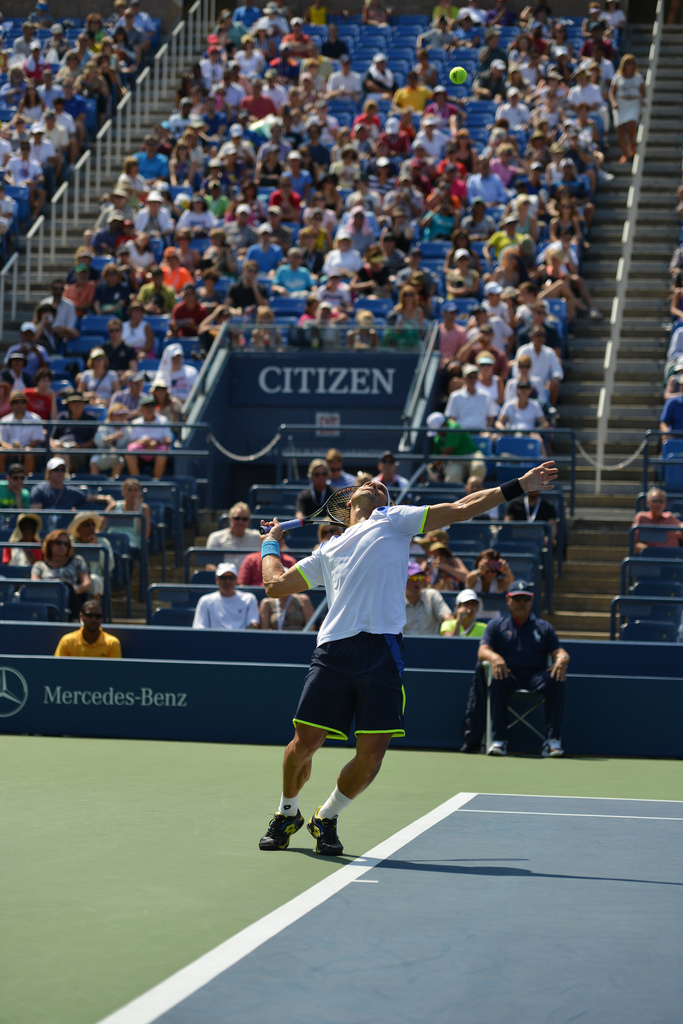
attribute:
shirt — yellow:
[36, 584, 112, 654]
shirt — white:
[173, 539, 274, 636]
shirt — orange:
[138, 238, 194, 312]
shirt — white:
[71, 521, 147, 573]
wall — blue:
[36, 654, 209, 735]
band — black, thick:
[473, 469, 541, 513]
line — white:
[126, 787, 660, 1013]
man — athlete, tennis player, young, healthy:
[327, 465, 461, 613]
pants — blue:
[288, 631, 444, 794]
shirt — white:
[255, 469, 508, 691]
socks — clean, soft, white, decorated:
[265, 769, 385, 835]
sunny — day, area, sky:
[19, 25, 628, 1011]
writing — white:
[262, 361, 399, 406]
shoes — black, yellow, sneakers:
[253, 806, 301, 847]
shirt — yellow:
[53, 597, 115, 658]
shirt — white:
[194, 559, 256, 629]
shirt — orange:
[160, 247, 192, 290]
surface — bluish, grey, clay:
[425, 855, 595, 985]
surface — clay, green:
[32, 787, 160, 927]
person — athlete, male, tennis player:
[140, 379, 512, 1022]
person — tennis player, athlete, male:
[130, 421, 568, 975]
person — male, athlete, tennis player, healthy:
[151, 403, 514, 886]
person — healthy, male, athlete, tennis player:
[139, 433, 572, 929]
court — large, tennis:
[40, 406, 619, 1015]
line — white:
[35, 803, 484, 1021]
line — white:
[429, 772, 662, 837]